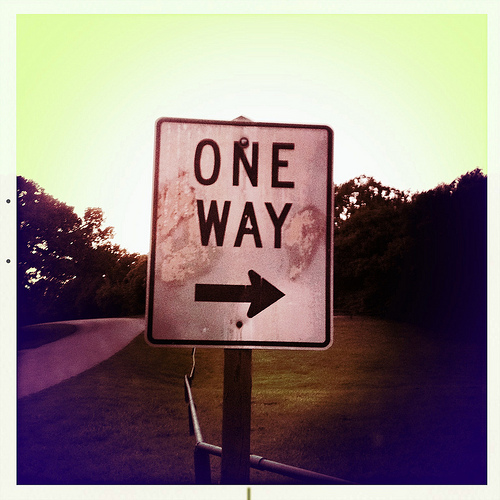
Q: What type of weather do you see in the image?
A: It is clear.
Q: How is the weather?
A: It is clear.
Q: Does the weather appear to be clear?
A: Yes, it is clear.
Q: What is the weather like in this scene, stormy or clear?
A: It is clear.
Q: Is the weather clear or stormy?
A: It is clear.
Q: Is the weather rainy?
A: No, it is clear.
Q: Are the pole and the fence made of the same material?
A: No, the pole is made of wood and the fence is made of metal.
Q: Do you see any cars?
A: No, there are no cars.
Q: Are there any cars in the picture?
A: No, there are no cars.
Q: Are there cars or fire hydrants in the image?
A: No, there are no cars or fire hydrants.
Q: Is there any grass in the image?
A: Yes, there is grass.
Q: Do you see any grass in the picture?
A: Yes, there is grass.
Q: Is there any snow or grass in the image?
A: Yes, there is grass.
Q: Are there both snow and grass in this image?
A: No, there is grass but no snow.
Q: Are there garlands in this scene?
A: No, there are no garlands.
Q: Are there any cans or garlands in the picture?
A: No, there are no garlands or cans.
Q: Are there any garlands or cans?
A: No, there are no garlands or cans.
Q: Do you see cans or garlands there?
A: No, there are no garlands or cans.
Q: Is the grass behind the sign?
A: Yes, the grass is behind the sign.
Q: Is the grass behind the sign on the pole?
A: Yes, the grass is behind the sign.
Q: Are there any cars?
A: No, there are no cars.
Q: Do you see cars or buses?
A: No, there are no cars or buses.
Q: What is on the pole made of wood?
A: The sign is on the pole.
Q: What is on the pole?
A: The sign is on the pole.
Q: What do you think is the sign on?
A: The sign is on the pole.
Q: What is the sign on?
A: The sign is on the pole.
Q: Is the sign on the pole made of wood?
A: Yes, the sign is on the pole.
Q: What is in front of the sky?
A: The sign is in front of the sky.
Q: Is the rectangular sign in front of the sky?
A: Yes, the sign is in front of the sky.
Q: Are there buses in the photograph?
A: No, there are no buses.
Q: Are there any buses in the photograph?
A: No, there are no buses.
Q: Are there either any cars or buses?
A: No, there are no buses or cars.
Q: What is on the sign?
A: The arrow is on the sign.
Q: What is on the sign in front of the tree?
A: The arrow is on the sign.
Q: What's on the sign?
A: The arrow is on the sign.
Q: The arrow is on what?
A: The arrow is on the sign.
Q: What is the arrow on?
A: The arrow is on the sign.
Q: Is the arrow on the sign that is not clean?
A: Yes, the arrow is on the sign.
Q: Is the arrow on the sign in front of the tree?
A: Yes, the arrow is on the sign.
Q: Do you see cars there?
A: No, there are no cars.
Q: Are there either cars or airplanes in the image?
A: No, there are no cars or airplanes.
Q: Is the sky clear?
A: Yes, the sky is clear.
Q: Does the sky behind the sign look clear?
A: Yes, the sky is clear.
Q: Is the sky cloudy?
A: No, the sky is clear.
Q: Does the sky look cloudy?
A: No, the sky is clear.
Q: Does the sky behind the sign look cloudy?
A: No, the sky is clear.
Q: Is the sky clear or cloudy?
A: The sky is clear.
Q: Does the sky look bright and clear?
A: Yes, the sky is bright and clear.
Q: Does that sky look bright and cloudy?
A: No, the sky is bright but clear.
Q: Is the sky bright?
A: Yes, the sky is bright.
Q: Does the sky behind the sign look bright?
A: Yes, the sky is bright.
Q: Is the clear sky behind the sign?
A: Yes, the sky is behind the sign.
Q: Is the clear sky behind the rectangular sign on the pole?
A: Yes, the sky is behind the sign.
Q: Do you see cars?
A: No, there are no cars.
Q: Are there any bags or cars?
A: No, there are no cars or bags.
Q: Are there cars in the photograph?
A: No, there are no cars.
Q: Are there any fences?
A: Yes, there is a fence.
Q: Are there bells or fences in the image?
A: Yes, there is a fence.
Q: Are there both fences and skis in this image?
A: No, there is a fence but no skis.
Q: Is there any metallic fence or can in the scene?
A: Yes, there is a metal fence.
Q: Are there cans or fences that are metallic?
A: Yes, the fence is metallic.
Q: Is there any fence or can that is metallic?
A: Yes, the fence is metallic.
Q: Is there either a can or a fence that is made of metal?
A: Yes, the fence is made of metal.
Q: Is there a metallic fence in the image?
A: Yes, there is a metal fence.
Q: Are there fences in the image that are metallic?
A: Yes, there is a fence that is metallic.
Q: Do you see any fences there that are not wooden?
A: Yes, there is a metallic fence.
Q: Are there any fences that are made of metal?
A: Yes, there is a fence that is made of metal.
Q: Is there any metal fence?
A: Yes, there is a fence that is made of metal.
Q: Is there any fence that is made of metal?
A: Yes, there is a fence that is made of metal.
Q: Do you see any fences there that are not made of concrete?
A: Yes, there is a fence that is made of metal.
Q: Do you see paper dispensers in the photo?
A: No, there are no paper dispensers.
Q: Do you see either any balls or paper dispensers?
A: No, there are no paper dispensers or balls.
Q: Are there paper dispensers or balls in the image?
A: No, there are no paper dispensers or balls.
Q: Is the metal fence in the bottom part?
A: Yes, the fence is in the bottom of the image.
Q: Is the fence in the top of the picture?
A: No, the fence is in the bottom of the image.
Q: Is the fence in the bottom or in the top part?
A: The fence is in the bottom of the image.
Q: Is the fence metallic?
A: Yes, the fence is metallic.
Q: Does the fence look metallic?
A: Yes, the fence is metallic.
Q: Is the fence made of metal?
A: Yes, the fence is made of metal.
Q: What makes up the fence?
A: The fence is made of metal.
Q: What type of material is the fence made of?
A: The fence is made of metal.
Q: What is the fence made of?
A: The fence is made of metal.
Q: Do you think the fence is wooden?
A: No, the fence is metallic.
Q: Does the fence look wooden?
A: No, the fence is metallic.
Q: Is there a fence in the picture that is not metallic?
A: No, there is a fence but it is metallic.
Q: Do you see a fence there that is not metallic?
A: No, there is a fence but it is metallic.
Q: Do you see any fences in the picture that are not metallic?
A: No, there is a fence but it is metallic.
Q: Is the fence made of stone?
A: No, the fence is made of metal.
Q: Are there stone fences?
A: No, there is a fence but it is made of metal.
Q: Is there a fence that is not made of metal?
A: No, there is a fence but it is made of metal.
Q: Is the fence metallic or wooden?
A: The fence is metallic.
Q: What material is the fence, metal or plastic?
A: The fence is made of metal.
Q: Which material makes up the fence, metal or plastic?
A: The fence is made of metal.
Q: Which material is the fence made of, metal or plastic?
A: The fence is made of metal.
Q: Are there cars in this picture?
A: No, there are no cars.